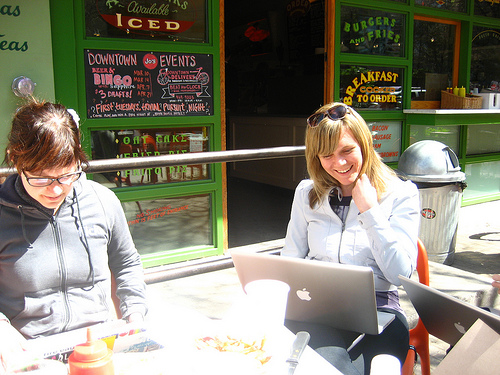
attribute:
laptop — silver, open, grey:
[235, 239, 387, 335]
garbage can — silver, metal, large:
[390, 137, 477, 272]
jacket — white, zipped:
[278, 191, 428, 284]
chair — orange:
[407, 245, 449, 374]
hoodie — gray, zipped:
[6, 180, 133, 304]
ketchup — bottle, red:
[64, 334, 115, 374]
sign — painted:
[67, 44, 219, 124]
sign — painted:
[336, 61, 414, 121]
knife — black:
[276, 329, 328, 374]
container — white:
[232, 276, 303, 342]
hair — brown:
[15, 115, 81, 162]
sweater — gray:
[4, 203, 127, 327]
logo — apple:
[291, 284, 321, 313]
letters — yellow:
[354, 71, 396, 88]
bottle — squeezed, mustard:
[92, 327, 131, 372]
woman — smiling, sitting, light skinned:
[277, 105, 415, 368]